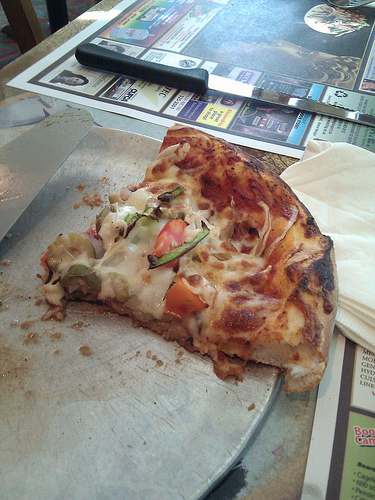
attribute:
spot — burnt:
[292, 250, 335, 294]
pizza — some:
[51, 113, 335, 378]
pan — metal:
[10, 287, 287, 499]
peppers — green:
[116, 180, 210, 261]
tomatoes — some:
[147, 206, 206, 323]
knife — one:
[79, 35, 373, 132]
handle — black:
[68, 31, 208, 87]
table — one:
[6, 8, 373, 470]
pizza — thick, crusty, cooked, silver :
[38, 114, 347, 388]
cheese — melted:
[98, 186, 211, 307]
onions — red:
[57, 216, 126, 263]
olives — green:
[49, 222, 109, 293]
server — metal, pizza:
[4, 96, 100, 280]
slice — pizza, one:
[63, 119, 333, 394]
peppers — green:
[118, 184, 212, 265]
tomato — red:
[152, 213, 190, 276]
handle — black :
[66, 29, 209, 101]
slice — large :
[31, 116, 350, 416]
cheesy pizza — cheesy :
[41, 111, 339, 406]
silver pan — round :
[0, 108, 289, 496]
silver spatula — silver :
[1, 102, 120, 290]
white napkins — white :
[267, 127, 373, 357]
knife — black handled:
[62, 33, 372, 138]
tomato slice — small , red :
[153, 280, 220, 320]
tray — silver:
[50, 312, 176, 436]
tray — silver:
[89, 371, 259, 482]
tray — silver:
[82, 351, 155, 477]